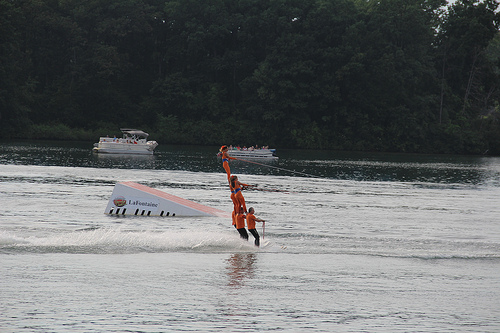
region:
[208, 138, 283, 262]
bunch of people doing pyramid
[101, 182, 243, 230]
a ramp on water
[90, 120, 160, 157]
a boat of people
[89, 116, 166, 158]
bunch of people on the boat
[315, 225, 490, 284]
a body of water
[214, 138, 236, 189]
a person on top of another person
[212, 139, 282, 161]
people on a boat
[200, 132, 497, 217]
person holding on a string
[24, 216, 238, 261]
water splashes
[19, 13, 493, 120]
bunch of tall trees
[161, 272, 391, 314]
calm waters of the lake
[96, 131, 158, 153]
a boat with people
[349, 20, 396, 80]
green leaves of a tree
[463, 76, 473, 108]
the trunk of a tree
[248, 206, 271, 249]
a man surfing on the water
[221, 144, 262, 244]
a group of 5 people surfing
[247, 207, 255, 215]
the head of a man surfing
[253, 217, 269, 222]
the hand of a person surfing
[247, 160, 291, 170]
a string being pulled by a surfer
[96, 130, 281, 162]
2 boats on the water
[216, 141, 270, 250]
pyramid of skiers on skis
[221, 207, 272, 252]
group of men on skis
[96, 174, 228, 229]
ramp leading out of the water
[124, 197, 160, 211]
words on side of ramp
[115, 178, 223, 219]
ramp in water is red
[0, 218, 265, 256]
wake of waves behind skiers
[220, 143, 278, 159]
boat full of people in distance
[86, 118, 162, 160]
pontoon boat in front of smaller boat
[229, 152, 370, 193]
woman pulling ski rope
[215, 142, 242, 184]
woman on top of pyramid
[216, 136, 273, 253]
people wind surfing in the water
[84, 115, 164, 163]
boat in the water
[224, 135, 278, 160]
people on the boat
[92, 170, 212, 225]
platform in the water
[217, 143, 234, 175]
woman with blue bikini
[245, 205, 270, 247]
man on a surf board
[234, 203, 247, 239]
person in black pants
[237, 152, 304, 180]
rope the woman is holding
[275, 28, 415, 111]
trees in the woods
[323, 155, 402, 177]
sparkling white water in the lake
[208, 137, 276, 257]
a group of people are jet skiing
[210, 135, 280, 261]
the people are in a pyramid formation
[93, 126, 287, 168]
two boats are on the water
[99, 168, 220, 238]
a ramp is in the water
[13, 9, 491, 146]
trees are in the background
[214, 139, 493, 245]
the group holds onto handles attached to a rope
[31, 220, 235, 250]
a trail of waves are behind the group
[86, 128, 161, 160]
the boat is white in color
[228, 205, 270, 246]
men are on the bottom of the pyramid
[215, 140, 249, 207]
women are in the middle and the top of the formation